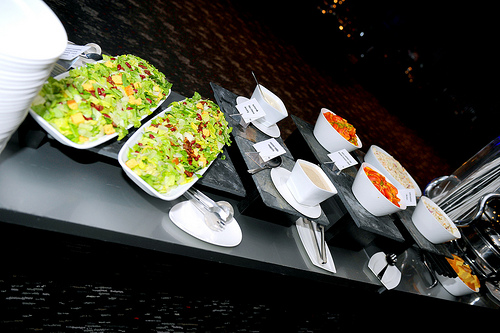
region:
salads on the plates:
[50, 25, 236, 223]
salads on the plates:
[53, 25, 220, 231]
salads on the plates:
[45, 20, 256, 244]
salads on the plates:
[25, 28, 235, 211]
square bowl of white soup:
[287, 158, 338, 205]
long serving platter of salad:
[116, 88, 233, 199]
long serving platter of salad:
[28, 53, 173, 152]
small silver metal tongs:
[186, 185, 235, 230]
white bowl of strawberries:
[351, 160, 406, 213]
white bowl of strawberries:
[313, 105, 360, 154]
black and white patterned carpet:
[45, 0, 453, 193]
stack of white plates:
[0, 0, 69, 157]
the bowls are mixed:
[21, 41, 252, 225]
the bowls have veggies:
[88, 65, 229, 207]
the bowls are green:
[81, 81, 215, 238]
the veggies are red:
[301, 85, 405, 185]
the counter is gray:
[30, 33, 375, 300]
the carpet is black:
[141, 27, 261, 91]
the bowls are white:
[302, 105, 403, 220]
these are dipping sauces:
[234, 110, 375, 230]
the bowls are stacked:
[11, 21, 46, 165]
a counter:
[40, 175, 95, 208]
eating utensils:
[203, 195, 235, 229]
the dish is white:
[166, 189, 178, 200]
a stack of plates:
[9, 38, 35, 111]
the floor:
[243, 40, 283, 58]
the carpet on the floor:
[296, 51, 332, 91]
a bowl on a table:
[297, 162, 339, 215]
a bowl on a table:
[237, 70, 282, 129]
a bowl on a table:
[325, 109, 360, 151]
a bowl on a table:
[354, 165, 415, 232]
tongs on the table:
[190, 191, 234, 227]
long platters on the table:
[38, 42, 243, 198]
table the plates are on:
[10, 38, 482, 299]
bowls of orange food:
[310, 92, 417, 214]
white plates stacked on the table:
[0, 3, 68, 181]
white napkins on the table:
[279, 220, 413, 287]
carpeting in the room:
[10, 1, 475, 331]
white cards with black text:
[232, 93, 287, 163]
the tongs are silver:
[303, 218, 325, 263]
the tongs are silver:
[185, 185, 230, 227]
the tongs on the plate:
[297, 216, 337, 273]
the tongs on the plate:
[165, 185, 240, 246]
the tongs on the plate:
[295, 216, 335, 269]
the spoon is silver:
[377, 251, 394, 278]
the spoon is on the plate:
[365, 247, 400, 288]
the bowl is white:
[285, 157, 335, 207]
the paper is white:
[326, 147, 356, 168]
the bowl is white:
[314, 106, 362, 154]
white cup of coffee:
[258, 137, 348, 226]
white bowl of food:
[315, 82, 361, 160]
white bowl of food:
[437, 243, 492, 305]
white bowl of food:
[361, 138, 430, 220]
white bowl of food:
[411, 177, 477, 277]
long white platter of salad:
[105, 90, 237, 205]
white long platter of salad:
[29, 47, 175, 165]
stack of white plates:
[0, 3, 77, 198]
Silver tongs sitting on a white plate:
[186, 185, 237, 231]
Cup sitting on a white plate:
[288, 157, 338, 205]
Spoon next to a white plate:
[246, 154, 283, 171]